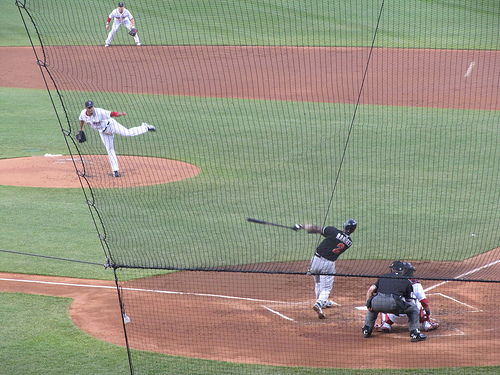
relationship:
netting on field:
[15, 2, 499, 375] [2, 1, 499, 375]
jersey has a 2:
[315, 225, 353, 264] [331, 243, 344, 253]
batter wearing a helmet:
[291, 218, 357, 318] [342, 220, 356, 232]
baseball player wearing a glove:
[76, 99, 154, 175] [76, 130, 87, 144]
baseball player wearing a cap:
[76, 99, 154, 175] [84, 100, 95, 110]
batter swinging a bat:
[291, 218, 357, 318] [246, 217, 298, 231]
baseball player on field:
[103, 2, 143, 47] [2, 1, 499, 375]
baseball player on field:
[76, 99, 154, 175] [2, 1, 499, 375]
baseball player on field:
[305, 216, 357, 317] [2, 1, 499, 375]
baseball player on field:
[380, 263, 439, 332] [2, 1, 499, 375]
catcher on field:
[359, 250, 424, 344] [2, 1, 499, 375]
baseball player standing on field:
[103, 2, 143, 47] [2, 1, 499, 375]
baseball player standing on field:
[76, 99, 154, 175] [2, 1, 499, 375]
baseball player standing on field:
[305, 216, 357, 317] [2, 1, 499, 375]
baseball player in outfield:
[103, 2, 143, 47] [2, 2, 499, 61]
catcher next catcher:
[359, 250, 424, 344] [359, 250, 424, 344]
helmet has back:
[342, 220, 356, 232] [346, 217, 353, 231]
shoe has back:
[311, 303, 324, 320] [361, 321, 371, 335]